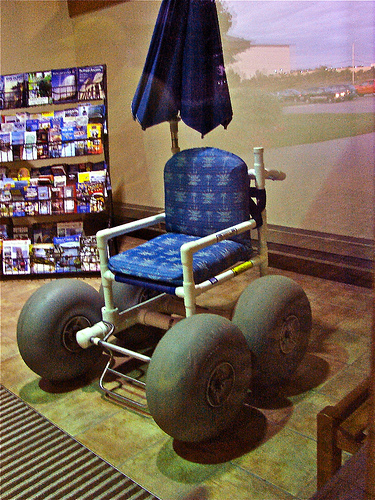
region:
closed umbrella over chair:
[128, 4, 236, 174]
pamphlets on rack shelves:
[11, 64, 107, 276]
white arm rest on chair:
[175, 216, 258, 274]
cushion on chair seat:
[114, 229, 214, 290]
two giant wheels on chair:
[145, 277, 314, 449]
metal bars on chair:
[94, 363, 145, 413]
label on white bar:
[210, 223, 242, 246]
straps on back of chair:
[243, 183, 268, 232]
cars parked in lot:
[290, 73, 367, 105]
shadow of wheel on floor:
[214, 404, 290, 472]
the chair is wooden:
[332, 413, 344, 436]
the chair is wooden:
[312, 421, 324, 439]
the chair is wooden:
[342, 400, 345, 430]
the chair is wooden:
[333, 396, 340, 429]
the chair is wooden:
[320, 415, 327, 435]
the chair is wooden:
[321, 419, 326, 443]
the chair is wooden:
[324, 429, 327, 452]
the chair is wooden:
[313, 432, 324, 458]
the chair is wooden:
[320, 430, 327, 451]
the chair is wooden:
[326, 424, 330, 447]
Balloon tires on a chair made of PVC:
[140, 312, 254, 446]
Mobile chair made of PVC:
[19, 149, 320, 424]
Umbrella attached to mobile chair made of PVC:
[136, 6, 234, 155]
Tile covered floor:
[320, 294, 360, 370]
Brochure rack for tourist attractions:
[0, 62, 113, 279]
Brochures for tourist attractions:
[0, 58, 108, 255]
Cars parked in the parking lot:
[285, 76, 362, 103]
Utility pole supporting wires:
[345, 40, 364, 86]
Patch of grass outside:
[287, 112, 353, 135]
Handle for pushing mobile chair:
[266, 161, 286, 191]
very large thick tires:
[36, 204, 315, 445]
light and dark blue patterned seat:
[92, 128, 280, 313]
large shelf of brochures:
[4, 55, 127, 301]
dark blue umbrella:
[111, 2, 252, 176]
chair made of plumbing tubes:
[71, 202, 247, 397]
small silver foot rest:
[85, 330, 199, 434]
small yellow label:
[228, 242, 260, 297]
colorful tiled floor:
[48, 194, 357, 492]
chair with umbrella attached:
[68, 5, 319, 306]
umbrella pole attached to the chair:
[143, 88, 208, 175]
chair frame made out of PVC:
[84, 215, 214, 339]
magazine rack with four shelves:
[4, 64, 127, 301]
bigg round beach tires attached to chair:
[140, 259, 351, 450]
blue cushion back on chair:
[143, 146, 267, 237]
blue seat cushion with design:
[108, 213, 243, 321]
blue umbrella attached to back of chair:
[105, 0, 248, 187]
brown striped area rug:
[2, 402, 124, 498]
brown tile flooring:
[100, 392, 284, 497]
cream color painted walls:
[10, 9, 68, 57]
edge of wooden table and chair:
[325, 380, 366, 495]